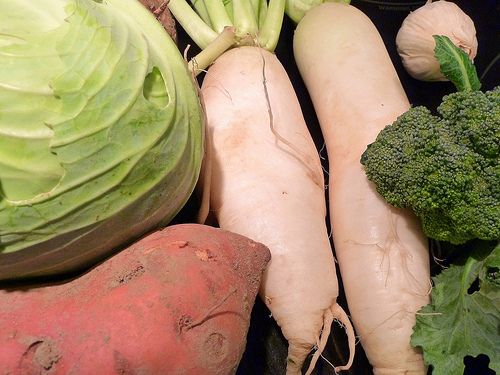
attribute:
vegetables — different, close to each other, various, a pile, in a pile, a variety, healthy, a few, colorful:
[1, 2, 498, 373]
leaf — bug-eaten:
[1, 1, 207, 279]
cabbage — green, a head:
[0, 1, 206, 279]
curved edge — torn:
[0, 0, 79, 213]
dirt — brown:
[36, 341, 60, 370]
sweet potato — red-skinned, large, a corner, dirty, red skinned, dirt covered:
[1, 222, 270, 374]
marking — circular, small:
[204, 333, 228, 361]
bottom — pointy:
[259, 256, 356, 375]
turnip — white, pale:
[201, 48, 357, 374]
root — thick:
[287, 341, 315, 374]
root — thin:
[304, 308, 334, 374]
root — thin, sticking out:
[332, 303, 357, 373]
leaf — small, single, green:
[434, 35, 480, 92]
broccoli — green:
[361, 85, 499, 241]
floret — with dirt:
[438, 86, 499, 154]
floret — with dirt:
[362, 106, 472, 213]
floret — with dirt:
[409, 143, 498, 245]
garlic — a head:
[395, 1, 477, 85]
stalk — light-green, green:
[166, 1, 217, 46]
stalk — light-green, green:
[205, 1, 232, 34]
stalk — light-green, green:
[233, 1, 258, 38]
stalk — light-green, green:
[258, 0, 287, 52]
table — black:
[0, 2, 499, 375]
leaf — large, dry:
[411, 244, 499, 373]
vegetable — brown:
[142, 1, 178, 43]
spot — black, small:
[117, 264, 145, 286]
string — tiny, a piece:
[259, 46, 313, 162]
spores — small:
[361, 85, 499, 247]